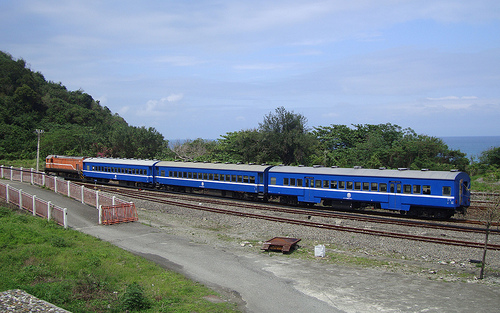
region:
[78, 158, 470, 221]
the train is blue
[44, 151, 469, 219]
one red car attached to blue cars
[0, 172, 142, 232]
a red and white fence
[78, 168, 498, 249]
the tracks are brown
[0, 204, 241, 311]
the grass is long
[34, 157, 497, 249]
the train is on the tracks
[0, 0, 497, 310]
the scene takes place outdoors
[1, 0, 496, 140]
wispy clouds in the sky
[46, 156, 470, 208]
the train has many windows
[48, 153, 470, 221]
the train is moving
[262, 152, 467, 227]
Long blue train cart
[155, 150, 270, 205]
Long blue train cart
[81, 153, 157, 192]
Long blue train cart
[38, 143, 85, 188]
Orange and white train engine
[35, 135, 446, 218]
Long train on tracks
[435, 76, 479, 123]
White clouds in the sky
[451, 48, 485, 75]
White clouds in the sky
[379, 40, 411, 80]
White clouds in the sky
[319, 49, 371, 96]
White clouds in the sky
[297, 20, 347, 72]
White clouds in the sky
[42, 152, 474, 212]
A blue and orange train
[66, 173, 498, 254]
brown railroad tracks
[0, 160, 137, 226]
Red and white fence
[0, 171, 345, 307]
grey concrete pathway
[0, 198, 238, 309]
patch of green grass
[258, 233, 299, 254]
piece of brown rusted metal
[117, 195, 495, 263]
patch of rocky grey gravel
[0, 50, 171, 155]
tall green bushes on a hill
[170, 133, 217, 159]
one dead brown bush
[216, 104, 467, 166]
green trees and brush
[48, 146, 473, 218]
passenger train on the train tracks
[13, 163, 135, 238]
fence with white posts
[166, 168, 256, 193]
windows on the side of a train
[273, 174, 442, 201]
windows on the side of a train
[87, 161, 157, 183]
windows on the side of a train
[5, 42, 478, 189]
trees lining the railroad tracks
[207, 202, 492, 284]
empty set of railroad tracks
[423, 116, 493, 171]
hill on the horizon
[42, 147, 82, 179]
red train engine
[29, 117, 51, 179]
electrical pole beside the train tracks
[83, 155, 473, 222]
a blue and grey train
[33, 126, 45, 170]
a train light pole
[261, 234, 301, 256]
a rusted flat truck bed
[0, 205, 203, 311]
a patch of green grass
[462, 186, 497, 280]
a small bare tree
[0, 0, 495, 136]
the blue sky with some white clouds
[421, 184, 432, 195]
a window on a train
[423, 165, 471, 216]
the front of a train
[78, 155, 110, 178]
the back of a train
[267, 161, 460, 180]
the roof of a train